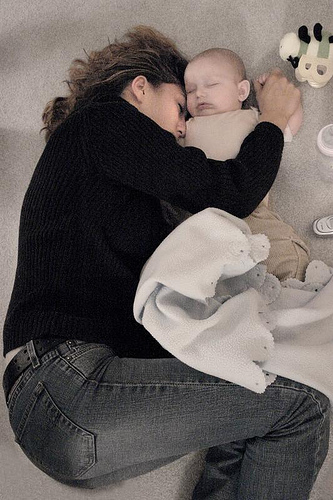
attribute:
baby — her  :
[161, 46, 310, 287]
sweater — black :
[4, 99, 282, 354]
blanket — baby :
[130, 205, 332, 408]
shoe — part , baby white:
[312, 214, 331, 239]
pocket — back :
[7, 398, 86, 483]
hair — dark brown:
[37, 21, 188, 97]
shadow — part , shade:
[3, 124, 40, 220]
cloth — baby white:
[131, 206, 332, 404]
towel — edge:
[132, 205, 332, 398]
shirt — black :
[2, 92, 285, 355]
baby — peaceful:
[177, 42, 259, 164]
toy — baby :
[273, 20, 331, 89]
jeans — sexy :
[11, 336, 322, 497]